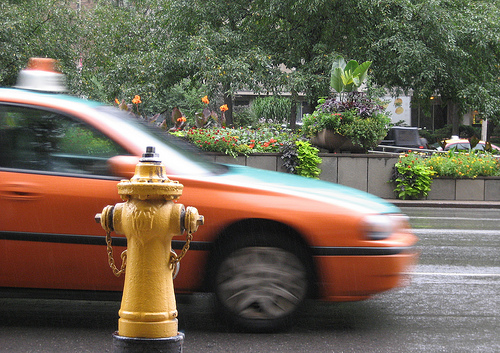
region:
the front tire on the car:
[220, 239, 304, 323]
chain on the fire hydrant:
[104, 252, 120, 273]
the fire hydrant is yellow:
[98, 149, 198, 346]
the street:
[435, 287, 499, 325]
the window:
[3, 109, 76, 168]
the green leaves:
[328, 61, 363, 92]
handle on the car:
[6, 182, 38, 201]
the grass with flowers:
[433, 155, 488, 176]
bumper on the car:
[385, 245, 416, 265]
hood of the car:
[263, 169, 336, 206]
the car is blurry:
[27, 160, 397, 317]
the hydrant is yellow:
[105, 205, 192, 340]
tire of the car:
[230, 215, 292, 313]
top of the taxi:
[3, 43, 74, 95]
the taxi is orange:
[207, 187, 282, 212]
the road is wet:
[435, 212, 496, 332]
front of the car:
[345, 193, 402, 293]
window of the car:
[8, 114, 139, 179]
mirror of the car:
[107, 147, 130, 179]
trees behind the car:
[90, 2, 443, 106]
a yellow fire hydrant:
[94, 143, 201, 349]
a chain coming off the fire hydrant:
[99, 233, 130, 275]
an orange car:
[9, 71, 428, 312]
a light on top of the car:
[23, 56, 67, 82]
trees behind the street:
[23, 16, 496, 93]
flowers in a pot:
[313, 83, 381, 141]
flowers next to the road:
[393, 147, 496, 182]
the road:
[378, 223, 498, 351]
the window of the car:
[2, 107, 122, 169]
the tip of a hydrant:
[139, 145, 159, 160]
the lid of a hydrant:
[115, 157, 177, 196]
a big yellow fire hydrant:
[98, 156, 193, 350]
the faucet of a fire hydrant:
[92, 208, 126, 235]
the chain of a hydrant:
[92, 234, 136, 278]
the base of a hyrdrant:
[105, 294, 187, 344]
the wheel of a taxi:
[223, 236, 308, 321]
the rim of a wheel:
[221, 251, 293, 316]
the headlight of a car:
[352, 193, 397, 243]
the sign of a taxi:
[21, 45, 58, 101]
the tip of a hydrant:
[128, 138, 163, 166]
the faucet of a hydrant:
[84, 203, 126, 235]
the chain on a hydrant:
[94, 226, 134, 278]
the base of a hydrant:
[107, 313, 188, 351]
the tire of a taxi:
[215, 232, 302, 329]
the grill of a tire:
[217, 258, 288, 318]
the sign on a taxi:
[17, 53, 68, 100]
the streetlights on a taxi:
[347, 188, 405, 249]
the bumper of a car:
[352, 236, 412, 296]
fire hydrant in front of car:
[90, 148, 201, 349]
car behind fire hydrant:
[1, 84, 412, 325]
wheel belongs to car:
[214, 231, 309, 331]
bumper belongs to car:
[320, 233, 417, 309]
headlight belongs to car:
[362, 214, 393, 246]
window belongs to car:
[2, 101, 136, 180]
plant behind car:
[298, 53, 390, 153]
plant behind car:
[394, 151, 431, 200]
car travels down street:
[2, 87, 414, 332]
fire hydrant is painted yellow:
[92, 144, 202, 349]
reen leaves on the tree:
[476, 11, 495, 57]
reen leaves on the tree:
[442, 25, 490, 75]